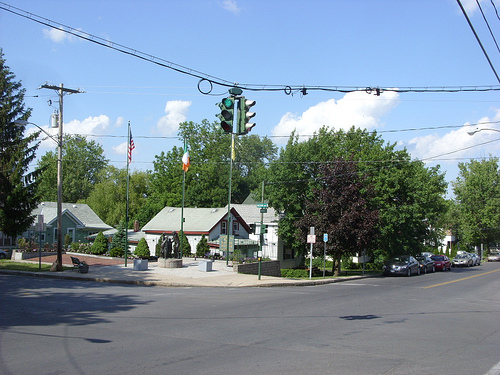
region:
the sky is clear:
[270, 38, 361, 67]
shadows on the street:
[306, 308, 416, 323]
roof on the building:
[152, 198, 227, 236]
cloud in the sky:
[286, 108, 372, 135]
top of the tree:
[278, 161, 380, 231]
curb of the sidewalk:
[199, 278, 253, 289]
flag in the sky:
[116, 128, 138, 169]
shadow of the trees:
[11, 287, 131, 329]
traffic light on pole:
[210, 93, 258, 140]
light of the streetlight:
[462, 127, 494, 139]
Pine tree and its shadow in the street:
[1, 48, 153, 340]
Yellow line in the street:
[411, 264, 498, 292]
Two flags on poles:
[122, 116, 192, 267]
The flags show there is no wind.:
[123, 119, 191, 179]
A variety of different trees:
[1, 47, 499, 284]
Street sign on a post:
[306, 226, 319, 278]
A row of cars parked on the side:
[382, 248, 483, 277]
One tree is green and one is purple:
[255, 122, 430, 279]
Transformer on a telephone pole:
[48, 113, 60, 128]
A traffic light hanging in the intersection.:
[214, 84, 258, 139]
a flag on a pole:
[118, 121, 136, 269]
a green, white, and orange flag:
[179, 132, 193, 176]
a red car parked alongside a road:
[428, 252, 454, 273]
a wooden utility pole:
[40, 81, 85, 275]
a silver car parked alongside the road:
[382, 253, 416, 278]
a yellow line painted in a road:
[418, 266, 499, 291]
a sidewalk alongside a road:
[2, 266, 66, 277]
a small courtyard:
[34, 244, 250, 282]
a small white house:
[137, 201, 258, 263]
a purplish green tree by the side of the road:
[297, 160, 378, 288]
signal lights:
[209, 76, 263, 152]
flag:
[124, 112, 136, 165]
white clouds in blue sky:
[320, 11, 377, 38]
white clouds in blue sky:
[298, 81, 368, 125]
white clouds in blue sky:
[410, 84, 464, 130]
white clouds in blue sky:
[100, 32, 149, 86]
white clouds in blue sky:
[126, 73, 188, 106]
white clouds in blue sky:
[15, 3, 90, 52]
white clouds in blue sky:
[300, 48, 355, 96]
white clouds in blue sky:
[232, 21, 299, 74]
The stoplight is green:
[197, 78, 243, 135]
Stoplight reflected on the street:
[329, 296, 389, 333]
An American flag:
[117, 108, 143, 160]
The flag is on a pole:
[120, 118, 144, 262]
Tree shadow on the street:
[8, 266, 118, 329]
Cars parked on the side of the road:
[382, 241, 479, 281]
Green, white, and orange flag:
[170, 128, 197, 240]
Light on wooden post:
[4, 113, 74, 147]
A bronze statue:
[152, 226, 185, 260]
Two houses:
[38, 198, 263, 250]